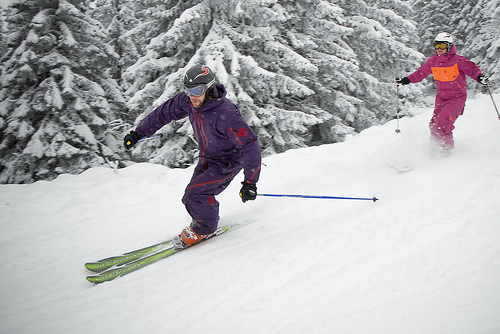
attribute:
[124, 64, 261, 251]
man — skiing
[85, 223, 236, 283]
skis — green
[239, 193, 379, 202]
pole — blue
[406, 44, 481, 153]
snowsuit — pink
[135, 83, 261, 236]
snowsuit — purple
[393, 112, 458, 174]
snow — flying, spraying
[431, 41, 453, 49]
goggles — orange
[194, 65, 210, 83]
markings — red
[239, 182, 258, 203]
glove — black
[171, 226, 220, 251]
boots — orange